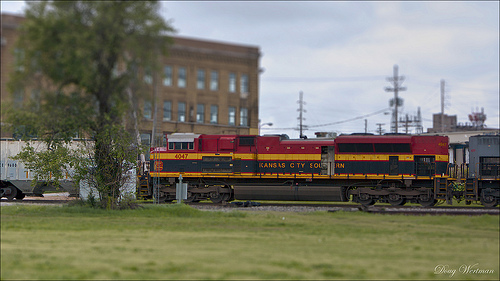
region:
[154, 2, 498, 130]
cloud cover in daytime sky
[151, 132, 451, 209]
side of train engine on tracks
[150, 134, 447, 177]
yellow line on side of train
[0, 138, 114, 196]
side of frieght car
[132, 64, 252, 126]
row of windows on two stories of building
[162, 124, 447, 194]
red yellow and black train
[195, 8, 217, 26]
white clouds in blue sky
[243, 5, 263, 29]
white clouds in blue sky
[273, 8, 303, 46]
white clouds in blue sky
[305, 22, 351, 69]
white clouds in blue sky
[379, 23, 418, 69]
white clouds in blue sky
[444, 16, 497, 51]
white clouds in blue sky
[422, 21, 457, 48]
white clouds in blue sky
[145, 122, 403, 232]
atrain on a track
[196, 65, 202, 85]
a window on a building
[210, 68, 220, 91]
a window on a building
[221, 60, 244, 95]
a window on a building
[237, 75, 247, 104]
a window on a building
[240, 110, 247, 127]
a window on a building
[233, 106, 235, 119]
a window on a building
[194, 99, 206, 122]
a window on a building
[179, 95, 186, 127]
a window on a building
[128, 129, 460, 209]
red and yellow train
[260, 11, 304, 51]
white clouds in blue sky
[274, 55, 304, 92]
white clouds in blue sky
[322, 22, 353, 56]
white clouds in blue sky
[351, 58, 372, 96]
white clouds in blue sky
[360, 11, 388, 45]
white clouds in blue sky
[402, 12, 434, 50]
white clouds in blue sky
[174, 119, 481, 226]
red blue and yellow train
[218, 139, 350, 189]
yellow name on train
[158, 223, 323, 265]
green grass near train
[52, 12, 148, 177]
tall tree near train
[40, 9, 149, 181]
green and leafy tree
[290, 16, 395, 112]
grey and white sky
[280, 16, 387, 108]
layers of clouds in sky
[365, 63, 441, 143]
telephone poles behind train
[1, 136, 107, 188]
grey car near train engine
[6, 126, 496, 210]
train engine between white and gray cars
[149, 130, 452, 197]
red, yellow and black stripes across engine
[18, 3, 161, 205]
tree with green leaves in front of train car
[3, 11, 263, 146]
brown building with flat roof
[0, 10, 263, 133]
A tall multiple story brick building.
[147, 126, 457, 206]
A red and yellow train car.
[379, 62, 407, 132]
A tall brown power pole.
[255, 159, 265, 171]
yellow letter on train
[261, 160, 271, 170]
yellow letter on train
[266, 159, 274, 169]
yellow letter on train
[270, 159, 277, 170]
yellow letter on train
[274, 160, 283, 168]
yellow letter on train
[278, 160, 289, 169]
yellow letter on train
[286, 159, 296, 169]
yellow letter on train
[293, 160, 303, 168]
yellow letter on train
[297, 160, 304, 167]
yellow letter on train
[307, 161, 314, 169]
yellow letter on train